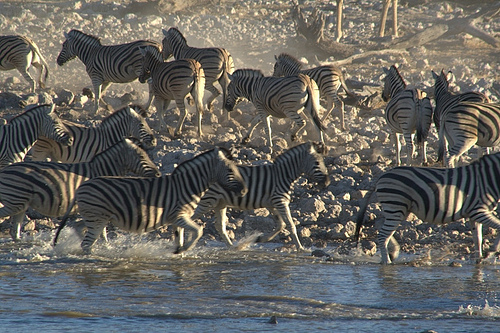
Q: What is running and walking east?
A: Six zebras.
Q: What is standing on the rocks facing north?
A: Two zebras.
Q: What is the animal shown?
A: Zebra.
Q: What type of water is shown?
A: A river.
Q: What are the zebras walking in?
A: A small body of water.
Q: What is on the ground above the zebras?
A: A large brown log.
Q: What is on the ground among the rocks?
A: Driftwood.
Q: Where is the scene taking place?
A: Next to a river.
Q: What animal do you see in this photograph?
A: Zebras.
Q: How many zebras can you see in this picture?
A: 16.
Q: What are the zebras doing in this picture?
A: Running out of the water.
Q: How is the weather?
A: Warm and dry.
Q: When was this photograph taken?
A: Early morning.